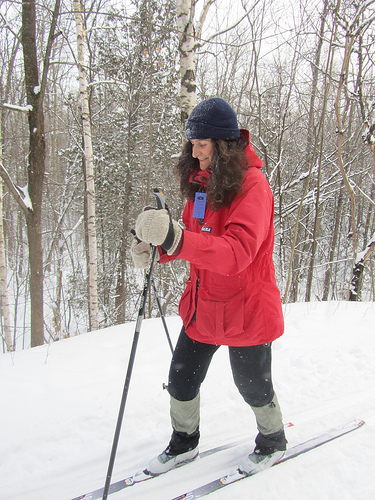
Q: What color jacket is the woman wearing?
A: Red.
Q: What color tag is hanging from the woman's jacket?
A: Purple.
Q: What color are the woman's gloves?
A: Tan.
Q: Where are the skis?
A: In the snow.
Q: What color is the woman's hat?
A: Navy blue.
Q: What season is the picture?
A: Winter.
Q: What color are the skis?
A: Silver.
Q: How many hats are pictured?
A: One.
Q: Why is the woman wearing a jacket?
A: Cold outside.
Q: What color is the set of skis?
A: Black.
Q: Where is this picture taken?
A: Snowy mountain top.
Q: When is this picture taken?
A: While skiing.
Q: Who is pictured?
A: A older woman.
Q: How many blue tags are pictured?
A: One.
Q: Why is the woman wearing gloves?
A: Cold outside.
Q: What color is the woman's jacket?
A: Red.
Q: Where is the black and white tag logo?
A: On red jacket.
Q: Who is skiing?
A: A woman.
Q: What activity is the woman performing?
A: Skiing.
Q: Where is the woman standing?
A: In the snow.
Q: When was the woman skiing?
A: During daylight hours.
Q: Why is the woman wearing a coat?
A: To keep warm.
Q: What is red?
A: Woman's jacket.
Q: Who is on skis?
A: A woman.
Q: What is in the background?
A: Trees.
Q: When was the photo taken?
A: Daytime.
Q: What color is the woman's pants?
A: Black.